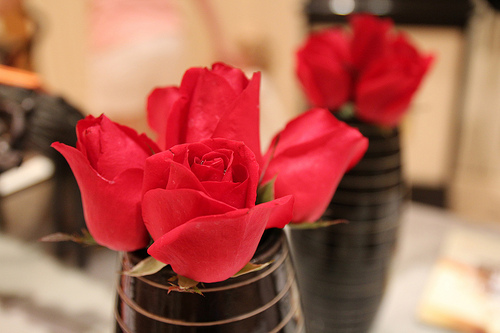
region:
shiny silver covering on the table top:
[395, 259, 447, 300]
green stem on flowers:
[32, 223, 101, 253]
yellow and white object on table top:
[418, 243, 485, 314]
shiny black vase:
[213, 294, 253, 305]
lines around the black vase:
[238, 278, 290, 313]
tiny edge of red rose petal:
[41, 132, 76, 155]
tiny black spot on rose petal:
[238, 207, 259, 224]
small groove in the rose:
[81, 167, 126, 195]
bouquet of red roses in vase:
[56, 67, 388, 272]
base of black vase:
[347, 189, 415, 231]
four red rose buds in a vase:
[52, 58, 377, 296]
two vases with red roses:
[91, 47, 413, 289]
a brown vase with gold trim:
[171, 287, 254, 331]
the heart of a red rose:
[186, 148, 234, 182]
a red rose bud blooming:
[259, 103, 373, 231]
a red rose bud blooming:
[141, 135, 284, 278]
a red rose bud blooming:
[52, 114, 147, 251]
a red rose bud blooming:
[164, 61, 267, 143]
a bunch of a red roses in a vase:
[302, 23, 434, 143]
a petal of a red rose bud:
[156, 199, 306, 280]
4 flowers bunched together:
[56, 60, 347, 291]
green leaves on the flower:
[245, 160, 335, 235]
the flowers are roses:
[5, 15, 362, 277]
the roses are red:
[53, 65, 347, 280]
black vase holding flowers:
[280, 114, 420, 314]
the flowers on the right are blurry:
[265, 11, 435, 298]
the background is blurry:
[15, 17, 135, 282]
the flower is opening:
[138, 126, 285, 291]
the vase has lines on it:
[115, 247, 305, 327]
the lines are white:
[79, 266, 316, 322]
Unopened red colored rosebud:
[263, 106, 358, 233]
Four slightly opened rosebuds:
[45, 46, 357, 286]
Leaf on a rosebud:
[115, 251, 163, 281]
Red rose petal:
[142, 192, 295, 286]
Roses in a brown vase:
[34, 50, 355, 330]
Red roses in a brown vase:
[43, 39, 372, 331]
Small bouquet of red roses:
[40, 54, 367, 306]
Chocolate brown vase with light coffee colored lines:
[106, 257, 348, 332]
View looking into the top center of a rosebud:
[188, 147, 242, 184]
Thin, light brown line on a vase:
[132, 307, 256, 330]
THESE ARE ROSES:
[52, 54, 374, 299]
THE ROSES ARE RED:
[49, 50, 370, 297]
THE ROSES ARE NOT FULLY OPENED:
[41, 46, 381, 291]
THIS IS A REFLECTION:
[288, 0, 453, 310]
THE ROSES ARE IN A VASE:
[43, 48, 370, 285]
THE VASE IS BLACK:
[98, 205, 306, 331]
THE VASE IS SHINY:
[96, 210, 313, 331]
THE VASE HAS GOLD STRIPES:
[99, 230, 315, 331]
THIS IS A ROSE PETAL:
[148, 191, 310, 286]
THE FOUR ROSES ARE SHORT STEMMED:
[63, 48, 378, 287]